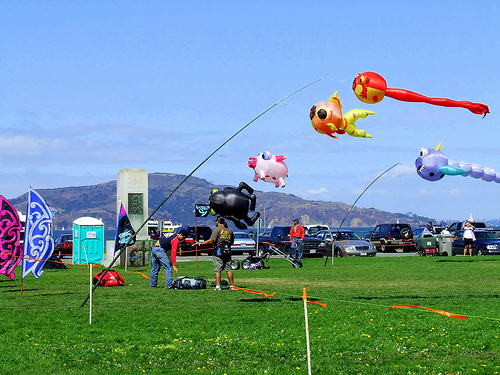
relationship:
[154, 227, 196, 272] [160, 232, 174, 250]
man wearing jacket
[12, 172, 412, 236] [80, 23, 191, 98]
hill under sky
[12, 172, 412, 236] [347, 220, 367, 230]
hill behind water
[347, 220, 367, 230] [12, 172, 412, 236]
water in front of hill